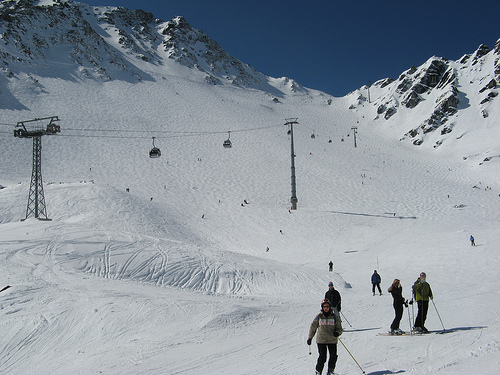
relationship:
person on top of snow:
[307, 299, 343, 374] [0, 1, 499, 374]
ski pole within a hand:
[334, 333, 366, 372] [334, 330, 341, 337]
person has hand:
[307, 299, 343, 374] [334, 330, 341, 337]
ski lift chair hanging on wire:
[150, 147, 162, 157] [54, 124, 289, 137]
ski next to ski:
[379, 293, 382, 295] [372, 293, 376, 295]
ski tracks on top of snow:
[75, 237, 249, 293] [0, 1, 499, 374]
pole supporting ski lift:
[284, 115, 298, 210] [0, 82, 372, 219]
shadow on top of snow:
[342, 327, 378, 332] [0, 1, 499, 374]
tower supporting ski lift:
[14, 115, 61, 222] [0, 82, 372, 219]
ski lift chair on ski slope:
[150, 147, 162, 157] [0, 78, 498, 374]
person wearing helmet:
[307, 299, 343, 374] [320, 297, 332, 307]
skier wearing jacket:
[386, 278, 409, 335] [384, 283, 405, 305]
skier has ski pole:
[386, 278, 409, 335] [405, 298, 415, 335]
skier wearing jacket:
[411, 270, 434, 330] [412, 279, 434, 303]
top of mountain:
[68, 0, 190, 32] [0, 1, 334, 100]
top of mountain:
[472, 34, 499, 56] [345, 35, 500, 160]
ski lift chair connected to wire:
[222, 140, 233, 149] [54, 124, 289, 137]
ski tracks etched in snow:
[75, 237, 249, 293] [0, 1, 499, 374]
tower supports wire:
[14, 115, 61, 222] [54, 124, 289, 137]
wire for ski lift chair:
[54, 124, 289, 137] [150, 147, 162, 157]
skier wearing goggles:
[323, 281, 342, 320] [328, 284, 333, 287]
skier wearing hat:
[323, 281, 342, 320] [328, 281, 333, 286]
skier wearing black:
[386, 278, 409, 335] [388, 283, 404, 328]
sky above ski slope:
[86, 0, 499, 98] [0, 78, 498, 374]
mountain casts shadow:
[0, 1, 334, 100] [241, 72, 286, 101]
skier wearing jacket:
[370, 269, 383, 293] [371, 272, 381, 286]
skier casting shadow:
[411, 270, 434, 330] [429, 325, 488, 336]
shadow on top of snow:
[429, 325, 488, 336] [0, 1, 499, 374]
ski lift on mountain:
[0, 82, 372, 219] [0, 1, 334, 100]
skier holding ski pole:
[411, 270, 434, 330] [431, 296, 446, 330]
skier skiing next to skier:
[386, 278, 409, 335] [411, 270, 434, 330]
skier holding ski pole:
[386, 278, 409, 335] [405, 298, 415, 335]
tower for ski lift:
[14, 115, 61, 222] [0, 82, 372, 219]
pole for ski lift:
[284, 115, 298, 210] [0, 82, 372, 219]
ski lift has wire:
[0, 82, 372, 219] [291, 121, 356, 143]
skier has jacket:
[411, 270, 434, 330] [412, 279, 434, 303]